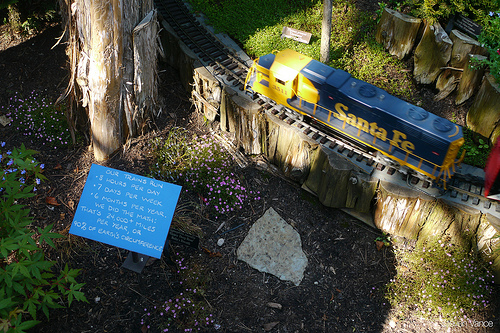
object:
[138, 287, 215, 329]
flowers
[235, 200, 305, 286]
rock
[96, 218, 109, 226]
words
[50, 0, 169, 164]
tree stump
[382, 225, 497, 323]
patch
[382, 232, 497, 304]
flowers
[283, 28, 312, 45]
information sign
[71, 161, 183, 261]
sign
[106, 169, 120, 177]
word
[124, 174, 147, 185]
word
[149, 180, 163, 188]
word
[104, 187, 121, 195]
word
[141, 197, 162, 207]
word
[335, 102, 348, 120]
letter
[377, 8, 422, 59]
bark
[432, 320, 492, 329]
credit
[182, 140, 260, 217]
flowers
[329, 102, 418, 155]
letter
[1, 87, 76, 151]
pink flowers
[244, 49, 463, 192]
train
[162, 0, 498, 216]
track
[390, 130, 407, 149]
letter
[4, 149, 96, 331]
plants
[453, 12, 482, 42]
card